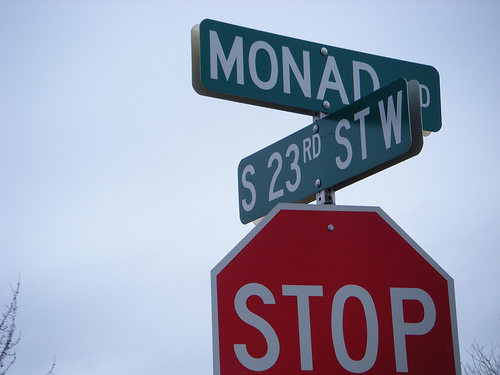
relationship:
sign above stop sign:
[236, 78, 425, 227] [209, 202, 462, 374]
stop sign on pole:
[209, 202, 462, 374] [314, 110, 337, 206]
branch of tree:
[0, 274, 21, 331] [1, 271, 60, 373]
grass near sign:
[462, 337, 499, 374] [236, 78, 425, 227]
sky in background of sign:
[2, 1, 500, 374] [189, 17, 442, 136]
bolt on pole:
[312, 124, 319, 133] [314, 110, 337, 206]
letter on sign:
[248, 39, 279, 91] [189, 17, 442, 136]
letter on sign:
[280, 42, 314, 97] [189, 17, 442, 136]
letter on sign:
[208, 28, 246, 86] [189, 17, 442, 136]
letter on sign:
[317, 53, 349, 103] [189, 17, 442, 136]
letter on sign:
[333, 118, 354, 170] [236, 78, 425, 227]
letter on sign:
[352, 106, 373, 161] [236, 78, 425, 227]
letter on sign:
[374, 88, 405, 148] [236, 78, 425, 227]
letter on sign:
[352, 58, 381, 103] [189, 17, 442, 136]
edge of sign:
[406, 78, 424, 154] [236, 78, 425, 227]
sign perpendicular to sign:
[236, 78, 425, 227] [189, 17, 442, 136]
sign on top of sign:
[189, 17, 442, 136] [236, 78, 425, 227]